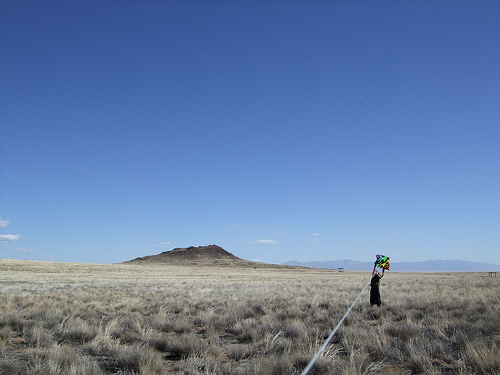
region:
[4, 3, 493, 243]
Sky is blue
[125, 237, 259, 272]
Small mountain on the field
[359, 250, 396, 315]
Person holding a kite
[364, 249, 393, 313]
Person hands up with a kite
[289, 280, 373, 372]
Rope of kite is white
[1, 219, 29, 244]
White clouds in the sky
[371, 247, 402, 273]
Kite is multicolor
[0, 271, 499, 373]
Field has dry grass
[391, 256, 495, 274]
Mountains in the background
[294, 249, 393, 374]
Kite is tied to a rope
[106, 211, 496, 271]
Mountains in background.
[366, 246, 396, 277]
Blue, red, black and yellow kite.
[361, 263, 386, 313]
Person in black outfit.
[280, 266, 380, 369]
White string attached to kite.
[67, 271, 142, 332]
Brown dry patches of grass.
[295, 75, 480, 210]
Clear blue sky.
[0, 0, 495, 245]
Wispy clouds in the sky.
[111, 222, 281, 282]
Brown mountain in the background.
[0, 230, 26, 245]
White clouds in the sky.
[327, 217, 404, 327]
Only one person in the field.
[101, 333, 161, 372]
dead grass on the ground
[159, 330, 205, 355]
dead grass on the ground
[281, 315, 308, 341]
dead grass on the ground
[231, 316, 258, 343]
dead grass on the ground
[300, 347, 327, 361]
dead grass on the ground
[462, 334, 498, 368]
dead grass on the ground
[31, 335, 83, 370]
dead grass on the ground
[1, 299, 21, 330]
dead grass on the ground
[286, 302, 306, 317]
dead grass on the ground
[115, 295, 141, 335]
dead grass on the ground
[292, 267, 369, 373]
White kite string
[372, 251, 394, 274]
Rainbow colored kite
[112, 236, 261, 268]
Mountain in the distance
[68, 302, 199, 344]
Brown grass on the ground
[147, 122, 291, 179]
Clear blue sky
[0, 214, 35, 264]
Group of three clouds in a blue sky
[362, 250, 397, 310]
Person holding a kite above their head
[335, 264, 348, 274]
Vehicle in the distance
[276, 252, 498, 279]
Mountains in the far distance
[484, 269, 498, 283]
Small building on the right side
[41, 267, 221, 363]
tall brown grass covering field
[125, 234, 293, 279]
large hill in the distance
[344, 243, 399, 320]
person about to release kite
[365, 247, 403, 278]
colorful kite held by person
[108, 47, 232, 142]
bright clear blue skies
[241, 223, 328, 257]
small wispy clouds in sky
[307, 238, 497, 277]
mountains in the distance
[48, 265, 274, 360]
very large field covered with brown grass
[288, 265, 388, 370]
white string attached to kite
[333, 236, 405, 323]
only one person visible in picture